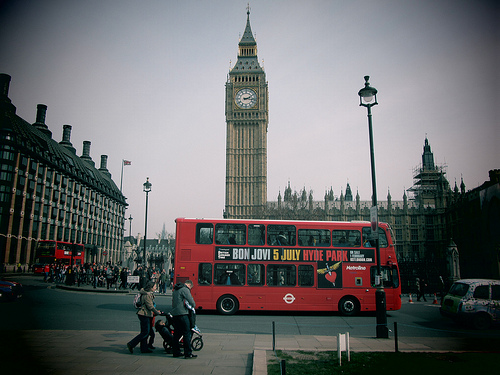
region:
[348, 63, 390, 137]
a light above the street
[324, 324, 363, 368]
a sign on the grass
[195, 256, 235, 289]
windows on a bus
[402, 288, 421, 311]
a cone in the street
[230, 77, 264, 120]
a clock on the building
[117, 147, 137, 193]
a flag on a pole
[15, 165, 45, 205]
a window on a building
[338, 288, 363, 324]
a tire on a bus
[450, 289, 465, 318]
tail light on a car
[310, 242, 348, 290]
a poster on the bus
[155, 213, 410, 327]
The bus is red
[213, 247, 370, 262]
the text is many colors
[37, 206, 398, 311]
there is a second bus in the back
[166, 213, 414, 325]
the bus has two stories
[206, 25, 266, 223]
The clocktower is tall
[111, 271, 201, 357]
people look at the bus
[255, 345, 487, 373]
The grass is wet and green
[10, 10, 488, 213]
The sky is partly cloudy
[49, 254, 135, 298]
Many people are walking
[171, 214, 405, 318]
A double decker bus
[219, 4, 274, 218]
Big Ben is standing tall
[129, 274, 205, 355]
Woman pushing a carriage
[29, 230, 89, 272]
A bus is red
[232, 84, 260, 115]
The clock is round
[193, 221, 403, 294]
Windows on side of the bus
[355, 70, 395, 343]
A tall street lamp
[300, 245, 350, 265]
The words "HYDE PARK" written in red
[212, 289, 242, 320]
A round black tire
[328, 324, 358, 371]
White sign on the grass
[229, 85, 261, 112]
Clock face on large tower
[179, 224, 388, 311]
Red double decker bus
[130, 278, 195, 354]
People walking pushing a stroller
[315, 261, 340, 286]
Red heart with sword and wings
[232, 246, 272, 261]
"BON JOVI" in white lettering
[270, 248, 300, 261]
"5 JULY" in yellow lettering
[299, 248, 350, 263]
"HYDE PARK" in red lettering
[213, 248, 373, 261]
Black ad sign on side of bus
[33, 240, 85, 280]
Red double decker bus in background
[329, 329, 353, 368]
Small white sign on grass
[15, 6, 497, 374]
picture taken outside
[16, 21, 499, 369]
picture taken during the day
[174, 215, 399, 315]
a bus is moving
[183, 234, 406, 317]
the bus is red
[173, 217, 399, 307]
a double decker bus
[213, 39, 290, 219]
the tower of london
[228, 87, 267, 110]
a clock on the tower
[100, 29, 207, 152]
the sky is void of clouds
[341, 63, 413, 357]
a street light is not lit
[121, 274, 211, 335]
people walking on the sidewalk